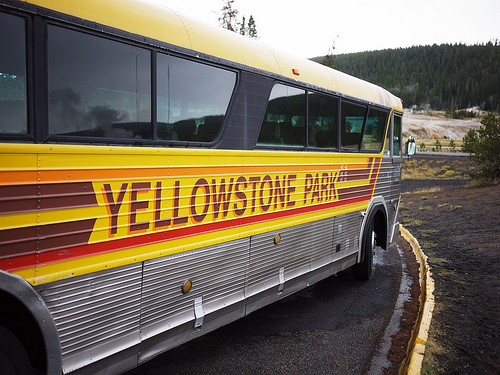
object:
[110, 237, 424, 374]
paved cement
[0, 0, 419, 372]
bus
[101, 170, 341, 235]
sign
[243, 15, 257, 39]
trees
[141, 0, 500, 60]
sky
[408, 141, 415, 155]
rearview mirror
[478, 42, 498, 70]
bushes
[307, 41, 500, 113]
mountain covered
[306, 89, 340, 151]
windows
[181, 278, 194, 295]
light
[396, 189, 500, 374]
soil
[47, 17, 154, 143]
window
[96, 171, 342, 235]
lettering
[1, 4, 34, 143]
windows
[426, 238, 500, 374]
green grass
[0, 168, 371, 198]
stripe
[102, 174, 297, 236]
word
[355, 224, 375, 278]
black tire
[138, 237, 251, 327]
door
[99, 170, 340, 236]
writing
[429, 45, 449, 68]
evergreen tree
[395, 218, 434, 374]
border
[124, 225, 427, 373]
road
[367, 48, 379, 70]
trees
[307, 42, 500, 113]
mountain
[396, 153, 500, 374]
dirt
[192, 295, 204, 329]
latch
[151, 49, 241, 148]
window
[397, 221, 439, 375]
curb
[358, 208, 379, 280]
wheel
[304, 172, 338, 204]
park.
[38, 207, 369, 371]
siding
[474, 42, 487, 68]
trees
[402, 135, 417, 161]
mirror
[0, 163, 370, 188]
orange stripe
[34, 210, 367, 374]
silver area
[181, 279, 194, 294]
reflector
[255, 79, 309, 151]
windows